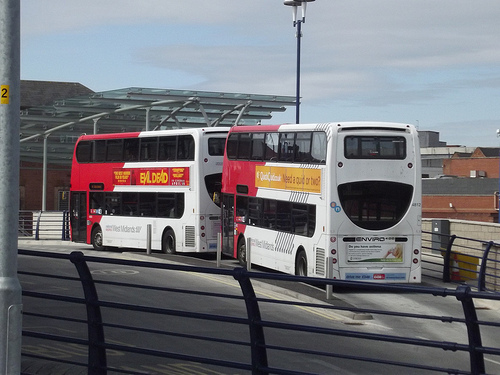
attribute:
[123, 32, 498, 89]
clouds — white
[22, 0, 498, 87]
sky — blue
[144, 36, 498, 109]
cloud — white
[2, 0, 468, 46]
cloud — white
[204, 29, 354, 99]
clouds — white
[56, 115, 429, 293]
bus — double-decker, red, white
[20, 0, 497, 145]
sky — blue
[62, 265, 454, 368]
railing — black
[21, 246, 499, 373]
rail — black, metal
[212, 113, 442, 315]
bus — black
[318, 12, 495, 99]
clouds — white